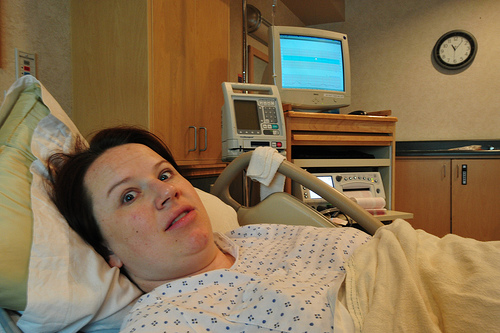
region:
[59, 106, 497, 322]
woman laying in the hospital bed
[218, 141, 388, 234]
bar on the hospital bed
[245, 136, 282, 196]
white cloth on the bar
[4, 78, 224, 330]
white pillowcase on the bed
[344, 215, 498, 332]
blanket covering the woman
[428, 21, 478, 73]
clock on the wall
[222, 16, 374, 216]
monitors next to woman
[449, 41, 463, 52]
black hands on the clock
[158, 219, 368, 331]
hospital gown woman is wearing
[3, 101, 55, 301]
green pillow on the bed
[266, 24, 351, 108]
a monitor is on a wood cabinet on wheels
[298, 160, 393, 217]
a fetal monitor is at the bedside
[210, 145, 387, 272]
the hospital bed rail is up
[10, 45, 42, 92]
emergency buttons are on the wall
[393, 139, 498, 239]
wood cabinets are in the room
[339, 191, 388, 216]
monitoring paper is left on the table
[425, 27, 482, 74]
a clock is on the wall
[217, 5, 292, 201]
the monitor is on an intravenous pole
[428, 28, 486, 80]
the clock is on the wall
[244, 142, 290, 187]
the washcloth is on the bed rail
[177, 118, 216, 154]
the cabinette handles are silver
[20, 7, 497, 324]
a patient is lying in bed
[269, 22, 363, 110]
the computer monitor is on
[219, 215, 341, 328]
the patient is wearing a gown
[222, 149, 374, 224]
the rail is up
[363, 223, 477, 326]
the blanket is tan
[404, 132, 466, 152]
the countertop is black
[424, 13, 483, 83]
the clock is black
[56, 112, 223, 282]
head of a person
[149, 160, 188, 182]
eye of a person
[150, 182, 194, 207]
nose of a person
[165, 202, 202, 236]
mouth of a person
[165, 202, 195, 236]
lip of a person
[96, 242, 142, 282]
ear of a person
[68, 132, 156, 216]
forehead of a person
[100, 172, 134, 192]
eyebrow of a person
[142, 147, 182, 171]
eyebrow of a person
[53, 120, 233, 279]
head of a person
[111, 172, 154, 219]
eye of a person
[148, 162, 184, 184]
eye of a person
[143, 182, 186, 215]
nose of a person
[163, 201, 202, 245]
mouth of a person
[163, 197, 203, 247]
lip of a person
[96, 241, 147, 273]
ear of a person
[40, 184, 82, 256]
hair of a person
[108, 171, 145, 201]
eyebrow of a person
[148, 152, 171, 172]
eyebrow of a person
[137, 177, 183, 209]
nose of a woman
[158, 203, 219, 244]
mouth of a woman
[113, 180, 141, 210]
eye of a woman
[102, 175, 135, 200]
eyebrow of a woman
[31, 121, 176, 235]
brown hair on a woman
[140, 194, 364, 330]
blue and white gown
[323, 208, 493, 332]
beige blanket on a woman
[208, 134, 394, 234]
plastic beige bed handle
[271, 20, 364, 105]
blue crt monitor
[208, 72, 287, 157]
a medical machine with screen and keys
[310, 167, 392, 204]
a medical machine with knobs and screen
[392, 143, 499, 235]
brown medical cabinet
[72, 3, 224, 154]
brown medical cabinet